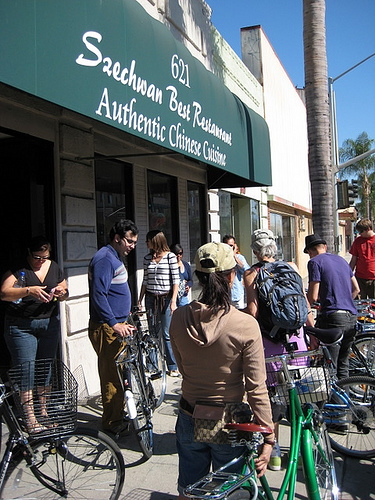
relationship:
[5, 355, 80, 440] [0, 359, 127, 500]
basket on bicycle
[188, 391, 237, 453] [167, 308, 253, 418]
bag on back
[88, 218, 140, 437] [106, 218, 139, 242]
cyclist has hair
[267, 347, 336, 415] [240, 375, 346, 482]
basket on bike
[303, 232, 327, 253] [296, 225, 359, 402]
black hat on man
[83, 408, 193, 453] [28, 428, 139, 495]
shadow of bicycle tire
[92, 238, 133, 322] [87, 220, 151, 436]
shirt on man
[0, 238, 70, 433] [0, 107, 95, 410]
cyclist standing by wall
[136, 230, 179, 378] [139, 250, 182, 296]
woman wearing shirt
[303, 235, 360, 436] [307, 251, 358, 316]
cyclist wearing purple shirt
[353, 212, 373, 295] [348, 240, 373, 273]
man wearing shirt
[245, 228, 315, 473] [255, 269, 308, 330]
cyclist with backpack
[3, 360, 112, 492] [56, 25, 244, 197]
cyclist gathered restaurant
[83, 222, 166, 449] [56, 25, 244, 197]
cyclist gathered restaurant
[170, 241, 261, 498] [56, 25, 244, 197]
cyclist gathered restaurant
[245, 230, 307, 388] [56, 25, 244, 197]
cyclist gathered restaurant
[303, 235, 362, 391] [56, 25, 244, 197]
cyclist gathered restaurant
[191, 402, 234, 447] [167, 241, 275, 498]
bag worn cyclist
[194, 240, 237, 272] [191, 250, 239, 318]
cap on hair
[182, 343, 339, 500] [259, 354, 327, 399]
bicycle has basket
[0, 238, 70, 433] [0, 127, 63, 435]
cyclist standing doorway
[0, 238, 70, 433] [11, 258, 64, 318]
cyclist wearing tee shirt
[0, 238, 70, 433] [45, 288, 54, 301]
cyclist holding phone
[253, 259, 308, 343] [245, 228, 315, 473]
backpack on cyclist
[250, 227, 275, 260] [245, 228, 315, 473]
hair on cyclist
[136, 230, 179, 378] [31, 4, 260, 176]
woman walking by restaurant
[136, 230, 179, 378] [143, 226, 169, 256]
woman has hair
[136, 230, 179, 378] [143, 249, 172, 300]
woman has shirt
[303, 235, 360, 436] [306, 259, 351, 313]
cyclist wearing shirt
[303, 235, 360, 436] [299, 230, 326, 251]
cyclist wearing hat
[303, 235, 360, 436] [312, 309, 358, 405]
cyclist wearing black jeans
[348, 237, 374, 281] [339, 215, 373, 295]
shirt on man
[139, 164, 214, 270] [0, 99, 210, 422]
windows on storefront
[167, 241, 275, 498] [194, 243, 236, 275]
cyclist wearing cap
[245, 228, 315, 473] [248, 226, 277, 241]
cyclist wearing cap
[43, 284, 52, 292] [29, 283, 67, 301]
phone in hand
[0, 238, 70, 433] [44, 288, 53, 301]
cyclist looking at phone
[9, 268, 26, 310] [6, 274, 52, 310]
water in arm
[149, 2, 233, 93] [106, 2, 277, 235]
shadow on building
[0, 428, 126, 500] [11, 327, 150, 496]
bicycle tire of bicycle